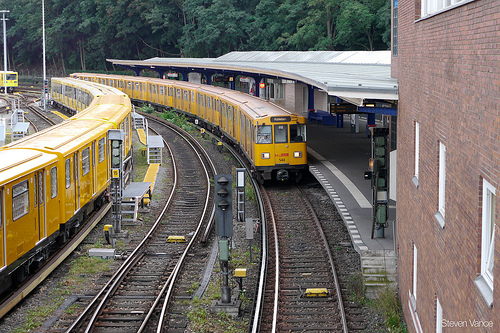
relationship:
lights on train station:
[257, 80, 267, 92] [6, 7, 414, 295]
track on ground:
[253, 183, 360, 331] [2, 100, 400, 332]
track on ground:
[68, 112, 218, 329] [2, 100, 400, 332]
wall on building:
[396, 3, 494, 330] [391, 0, 496, 330]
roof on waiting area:
[99, 45, 396, 110] [125, 55, 390, 205]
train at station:
[68, 70, 308, 185] [119, 31, 411, 241]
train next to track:
[68, 70, 308, 185] [68, 112, 218, 333]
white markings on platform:
[308, 149, 375, 257] [299, 112, 391, 257]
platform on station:
[288, 115, 400, 253] [101, 43, 402, 298]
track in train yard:
[68, 112, 218, 333] [0, 70, 405, 332]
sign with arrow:
[362, 169, 373, 182] [363, 173, 370, 177]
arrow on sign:
[213, 184, 252, 274] [190, 243, 283, 322]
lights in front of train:
[251, 150, 301, 165] [3, 57, 337, 249]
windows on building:
[410, 120, 419, 188] [390, 32, 498, 135]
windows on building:
[430, 138, 444, 225] [390, 32, 498, 135]